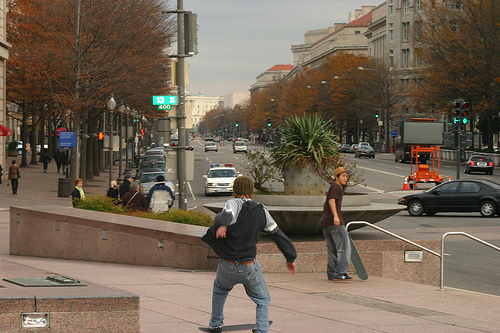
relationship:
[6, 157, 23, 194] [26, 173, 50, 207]
person walking sidewalk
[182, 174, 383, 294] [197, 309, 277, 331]
kid on skate board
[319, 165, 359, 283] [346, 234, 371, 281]
man with skate board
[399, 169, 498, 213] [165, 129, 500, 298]
car driving down busy street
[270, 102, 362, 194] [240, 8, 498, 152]
bush in middle of city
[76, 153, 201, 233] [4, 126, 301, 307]
group gathered at curb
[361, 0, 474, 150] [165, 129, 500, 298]
building lines busy street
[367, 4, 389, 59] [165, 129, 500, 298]
building lines busy street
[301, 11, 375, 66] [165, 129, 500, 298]
building lines busy street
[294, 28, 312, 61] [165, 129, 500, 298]
building lines busy street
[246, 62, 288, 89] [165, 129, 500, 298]
building lines busy street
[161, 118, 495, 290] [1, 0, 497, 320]
busy street in city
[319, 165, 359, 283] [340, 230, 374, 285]
man holding skateboard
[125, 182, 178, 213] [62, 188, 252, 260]
two people sitting on planter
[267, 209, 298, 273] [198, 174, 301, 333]
arm of kid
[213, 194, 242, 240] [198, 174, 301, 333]
arm of kid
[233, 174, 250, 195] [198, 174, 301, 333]
hair of kid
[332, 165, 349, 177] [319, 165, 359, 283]
tan hat of man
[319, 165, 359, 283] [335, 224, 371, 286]
man holding skateboard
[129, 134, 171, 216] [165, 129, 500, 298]
cars parked on busy street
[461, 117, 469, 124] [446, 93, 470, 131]
light on stoplight